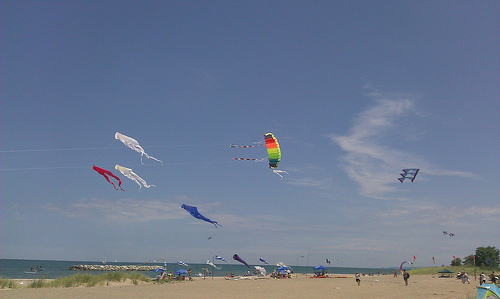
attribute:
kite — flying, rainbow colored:
[229, 133, 289, 179]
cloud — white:
[322, 80, 481, 199]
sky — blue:
[0, 0, 498, 269]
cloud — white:
[39, 193, 257, 235]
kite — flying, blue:
[180, 204, 223, 230]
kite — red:
[93, 164, 122, 192]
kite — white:
[114, 132, 164, 168]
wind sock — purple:
[232, 254, 253, 270]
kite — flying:
[398, 168, 419, 183]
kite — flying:
[114, 164, 157, 191]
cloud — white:
[374, 199, 499, 241]